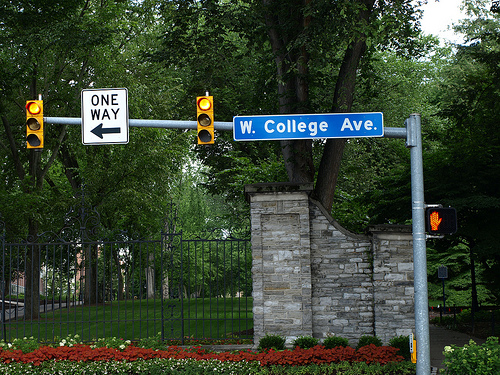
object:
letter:
[353, 120, 363, 130]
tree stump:
[359, 341, 402, 362]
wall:
[243, 183, 422, 347]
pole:
[384, 127, 406, 138]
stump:
[145, 293, 161, 300]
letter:
[287, 119, 291, 132]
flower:
[444, 346, 454, 354]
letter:
[240, 120, 253, 134]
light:
[196, 96, 214, 145]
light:
[26, 100, 44, 150]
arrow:
[90, 123, 121, 139]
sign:
[80, 87, 129, 145]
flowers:
[0, 331, 405, 368]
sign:
[232, 112, 384, 142]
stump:
[84, 301, 105, 305]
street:
[1, 297, 81, 325]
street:
[431, 317, 491, 371]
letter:
[292, 119, 296, 132]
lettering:
[237, 118, 377, 137]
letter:
[308, 122, 317, 137]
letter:
[297, 122, 306, 133]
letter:
[341, 118, 355, 132]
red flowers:
[3, 338, 404, 368]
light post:
[17, 81, 462, 375]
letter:
[277, 122, 286, 133]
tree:
[0, 0, 500, 319]